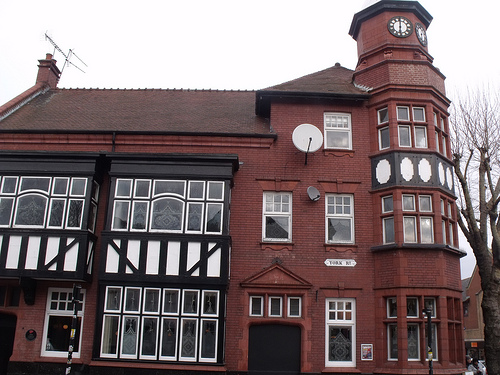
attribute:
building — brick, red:
[4, 5, 470, 375]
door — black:
[250, 322, 301, 374]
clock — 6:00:
[389, 13, 409, 39]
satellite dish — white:
[291, 120, 322, 166]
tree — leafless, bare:
[450, 91, 500, 370]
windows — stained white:
[116, 180, 220, 233]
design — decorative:
[372, 149, 458, 189]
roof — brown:
[10, 57, 363, 138]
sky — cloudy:
[3, 2, 495, 114]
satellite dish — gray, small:
[305, 183, 323, 206]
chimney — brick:
[36, 54, 67, 90]